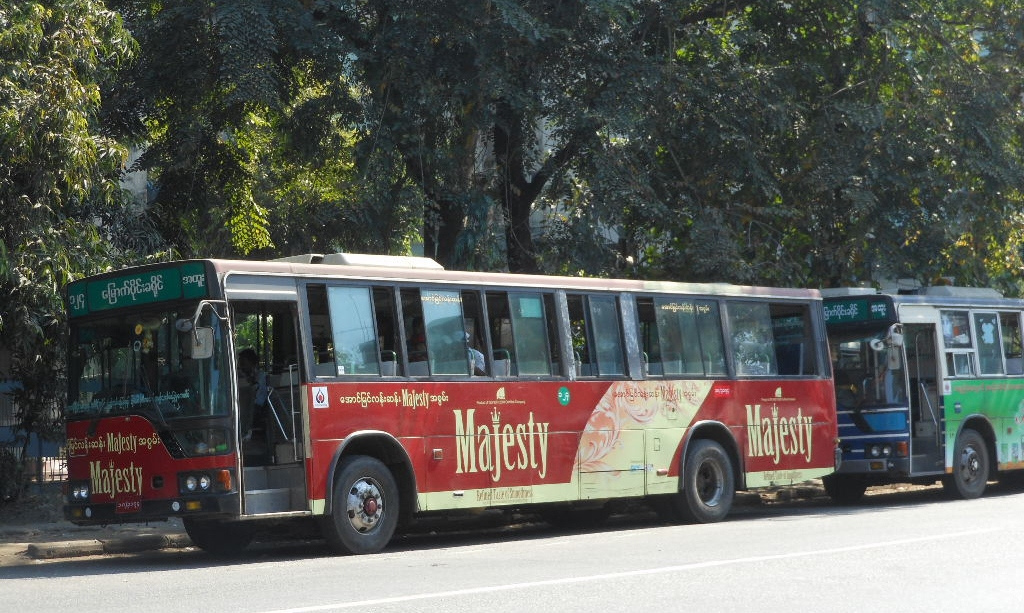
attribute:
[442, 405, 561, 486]
logo — Majesty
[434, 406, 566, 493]
logo — majesty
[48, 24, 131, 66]
leaves — green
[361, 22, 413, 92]
leaves — green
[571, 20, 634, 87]
leaves — green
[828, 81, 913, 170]
leaves — green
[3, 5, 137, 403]
trees — brown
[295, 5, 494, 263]
trees — brown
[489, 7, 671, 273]
trees — brown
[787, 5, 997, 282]
trees — brown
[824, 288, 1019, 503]
bus — large, green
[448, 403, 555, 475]
logo — majesty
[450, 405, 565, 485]
logo — majesty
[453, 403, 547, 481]
logo — majesty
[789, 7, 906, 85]
leaves — green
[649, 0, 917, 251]
tree — brown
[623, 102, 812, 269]
tree — brown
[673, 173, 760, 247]
leaves — green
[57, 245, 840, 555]
bus — red, large, white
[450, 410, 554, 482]
logo — Majesty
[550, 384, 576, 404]
sticker — round, green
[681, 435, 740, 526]
tire — black, missing hubcap